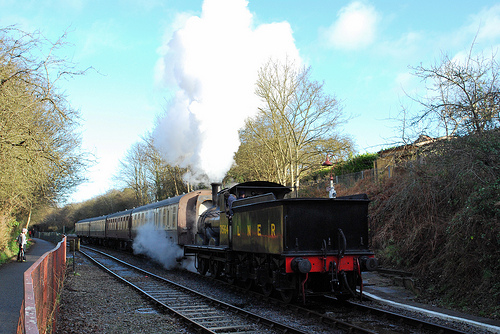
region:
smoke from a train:
[153, 74, 247, 182]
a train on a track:
[69, 179, 375, 306]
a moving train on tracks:
[60, 175, 381, 309]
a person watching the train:
[14, 222, 29, 263]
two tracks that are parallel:
[63, 233, 463, 329]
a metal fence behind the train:
[284, 141, 427, 190]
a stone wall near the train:
[16, 219, 72, 331]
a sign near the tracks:
[65, 230, 83, 268]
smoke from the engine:
[131, 219, 192, 276]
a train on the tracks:
[68, 175, 375, 305]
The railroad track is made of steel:
[83, 240, 291, 330]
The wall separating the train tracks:
[6, 228, 73, 330]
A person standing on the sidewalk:
[11, 220, 31, 264]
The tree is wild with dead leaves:
[4, 20, 100, 238]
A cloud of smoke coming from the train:
[153, 1, 305, 183]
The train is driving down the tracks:
[70, 175, 399, 305]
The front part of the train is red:
[281, 249, 379, 276]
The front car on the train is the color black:
[198, 178, 371, 250]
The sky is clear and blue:
[53, 14, 148, 153]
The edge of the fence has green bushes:
[298, 150, 374, 185]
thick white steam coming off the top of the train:
[144, 5, 308, 197]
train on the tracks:
[65, 173, 375, 307]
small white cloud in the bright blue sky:
[322, 0, 380, 57]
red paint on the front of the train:
[284, 253, 365, 275]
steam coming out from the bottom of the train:
[122, 218, 214, 272]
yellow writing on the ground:
[219, 216, 284, 243]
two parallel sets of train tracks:
[64, 216, 499, 327]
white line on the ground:
[357, 271, 491, 331]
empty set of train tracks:
[78, 243, 285, 330]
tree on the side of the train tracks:
[2, 29, 111, 288]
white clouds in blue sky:
[42, 13, 102, 51]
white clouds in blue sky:
[66, 5, 148, 53]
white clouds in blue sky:
[66, 101, 121, 153]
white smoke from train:
[175, 32, 222, 107]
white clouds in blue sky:
[305, 8, 380, 58]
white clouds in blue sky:
[349, 38, 383, 109]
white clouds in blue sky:
[372, 15, 440, 63]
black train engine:
[189, 163, 369, 303]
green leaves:
[12, 129, 59, 191]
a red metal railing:
[23, 228, 66, 332]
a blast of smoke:
[132, 220, 183, 267]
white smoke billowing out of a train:
[155, 0, 295, 176]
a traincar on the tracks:
[132, 188, 214, 262]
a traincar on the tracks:
[106, 204, 131, 248]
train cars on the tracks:
[72, 213, 106, 244]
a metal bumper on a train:
[290, 255, 312, 276]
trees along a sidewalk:
[0, 23, 85, 258]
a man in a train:
[221, 187, 237, 222]